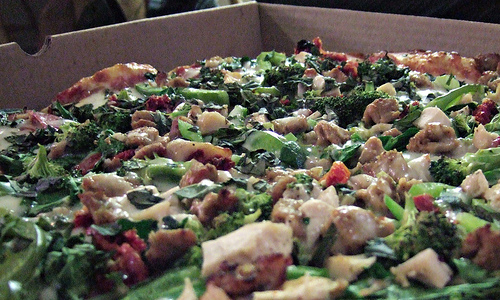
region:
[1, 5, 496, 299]
food in a cardboard box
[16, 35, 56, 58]
cutout in the cardboard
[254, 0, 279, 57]
corner of the box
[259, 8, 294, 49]
shadow on the box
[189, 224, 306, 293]
hunk of meat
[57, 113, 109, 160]
dark green broccoli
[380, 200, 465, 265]
green piece of broccoli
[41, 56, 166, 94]
food is curling up at the edge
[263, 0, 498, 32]
edge of the box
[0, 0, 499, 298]
no lid on the box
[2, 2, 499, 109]
A cardboard box is brown.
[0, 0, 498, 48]
The surface in the background has stripes.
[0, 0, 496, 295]
A pizza box has a loaded pizza in it.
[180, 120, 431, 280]
Pieces of chicken are with chunks of broccoli.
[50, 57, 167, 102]
A piece of cheese crust is against cardboard.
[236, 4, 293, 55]
A diagonal shadow is in the corner.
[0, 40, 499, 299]
There are lots of green veggies in this field of food.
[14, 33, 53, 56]
A half circle opening in a tan surface.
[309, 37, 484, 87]
Yellow cheese behind green veggies.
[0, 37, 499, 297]
Some reddish pieces of meat are mixed in the food.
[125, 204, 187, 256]
topping on the pizza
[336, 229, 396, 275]
topping on the pizza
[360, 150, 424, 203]
topping on the pizza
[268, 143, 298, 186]
topping on the pizza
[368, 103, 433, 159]
topping on the pizza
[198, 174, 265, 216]
topping on the pizza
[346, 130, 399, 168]
topping on the pizza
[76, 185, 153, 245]
topping on the pizza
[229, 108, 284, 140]
topping on the pizza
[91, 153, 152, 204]
topping on the pizza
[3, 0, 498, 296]
gooful goopy dish in a cardboard box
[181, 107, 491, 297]
way too many chunks of a meat that is probably chicken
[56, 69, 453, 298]
considering the dominant vegetables, there *is* a 10% chance that the meat is fake [one would hope]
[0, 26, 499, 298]
gloppy business is actually a pizza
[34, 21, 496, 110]
note crust in background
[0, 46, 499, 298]
someone has a heavy hand with the toppings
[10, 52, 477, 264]
theres broccoli on this, for certain. i see florets, many multiples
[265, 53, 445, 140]
florets beneath cheese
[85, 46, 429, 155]
i hate to say this, but it also includes the painfully trendy 'kale' [& i've been a vegetarian forever]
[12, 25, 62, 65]
a little round semicircle of a notch in a big square box